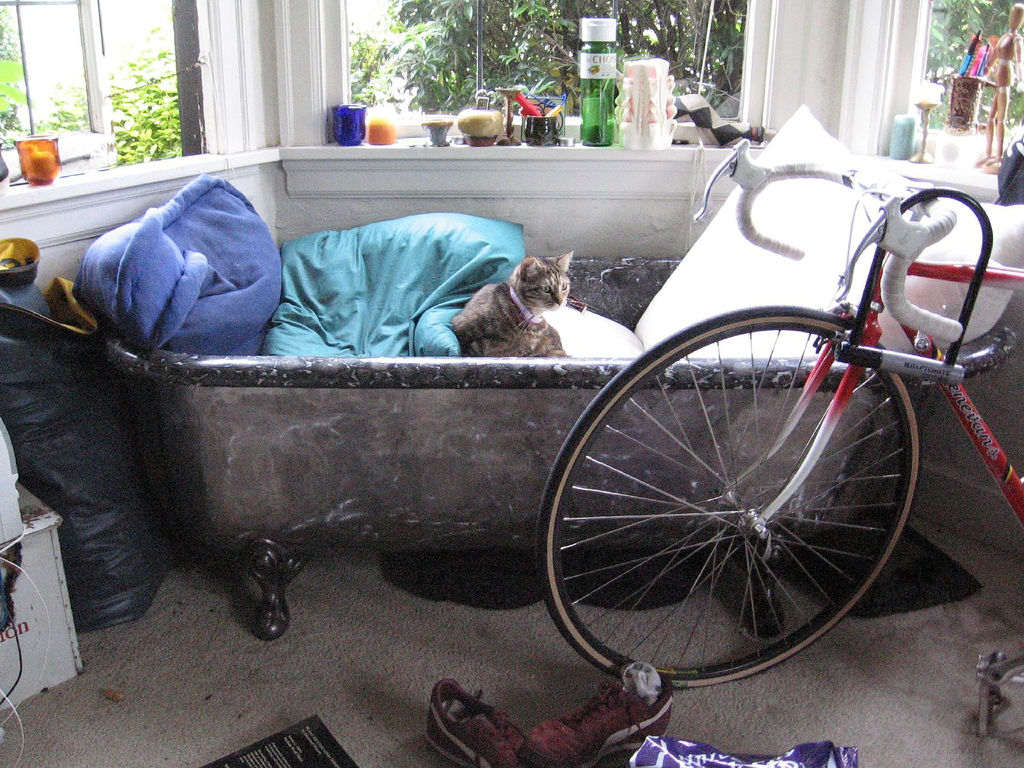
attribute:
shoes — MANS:
[421, 651, 687, 764]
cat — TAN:
[445, 243, 608, 356]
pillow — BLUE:
[75, 171, 292, 362]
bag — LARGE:
[0, 299, 173, 634]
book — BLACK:
[186, 709, 379, 764]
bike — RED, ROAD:
[527, 135, 1022, 741]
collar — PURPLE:
[493, 273, 554, 343]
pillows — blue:
[80, 147, 562, 403]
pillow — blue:
[85, 169, 293, 398]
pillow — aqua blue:
[270, 219, 526, 369]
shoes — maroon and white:
[415, 644, 683, 761]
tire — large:
[527, 286, 942, 727]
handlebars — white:
[711, 134, 992, 385]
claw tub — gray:
[98, 290, 883, 666]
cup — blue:
[316, 96, 388, 149]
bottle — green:
[571, 5, 634, 140]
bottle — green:
[577, 1, 627, 155]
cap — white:
[573, 13, 623, 50]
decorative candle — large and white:
[607, 41, 688, 167]